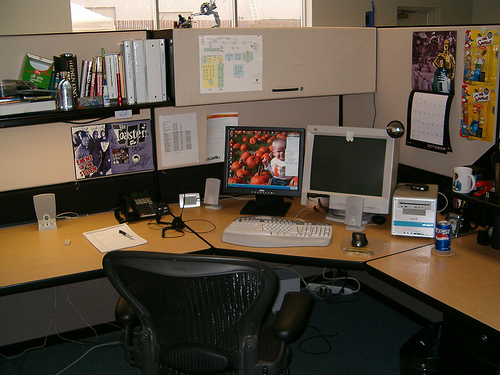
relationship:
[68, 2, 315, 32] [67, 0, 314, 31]
window showing outside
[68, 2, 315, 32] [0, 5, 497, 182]
window in background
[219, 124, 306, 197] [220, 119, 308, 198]
monitor with trim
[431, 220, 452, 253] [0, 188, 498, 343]
soda can sitting on desk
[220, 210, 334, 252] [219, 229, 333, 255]
keyboard has wrist rest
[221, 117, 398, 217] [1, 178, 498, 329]
monitors on desk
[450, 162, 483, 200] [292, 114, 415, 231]
mug to right of computer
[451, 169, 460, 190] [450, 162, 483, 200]
picture on mug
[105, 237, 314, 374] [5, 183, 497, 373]
chair by desk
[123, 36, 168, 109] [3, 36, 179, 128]
binders on shelf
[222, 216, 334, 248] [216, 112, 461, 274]
keyboard for computer